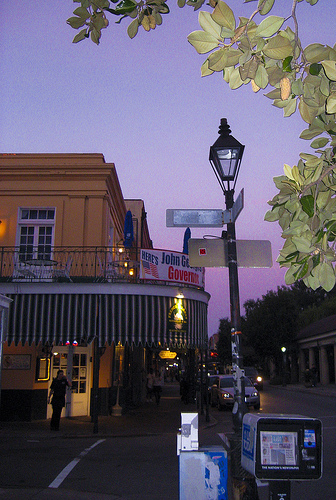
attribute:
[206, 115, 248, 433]
street light — metal, bright, white, tall, iron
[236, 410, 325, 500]
newspaper stand — silver, coin-operated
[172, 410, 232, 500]
newspaper stand — blue, metal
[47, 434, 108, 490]
line — faded, white, painted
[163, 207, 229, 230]
street sign — silver, white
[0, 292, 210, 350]
banner — black, striped, white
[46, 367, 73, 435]
woman — walking, standing, drinking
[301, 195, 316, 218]
leaf — green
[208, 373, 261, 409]
car — volvo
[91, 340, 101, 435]
pillar — concrete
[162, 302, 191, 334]
sign — green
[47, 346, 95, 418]
door — white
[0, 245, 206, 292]
fence — iron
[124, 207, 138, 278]
umbrella — folded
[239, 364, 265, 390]
car — driving